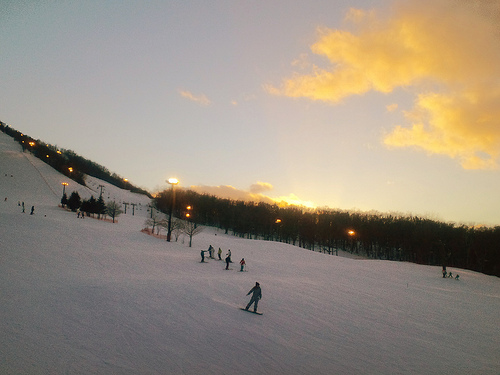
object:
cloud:
[262, 3, 497, 181]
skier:
[239, 257, 246, 272]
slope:
[1, 127, 499, 374]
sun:
[269, 194, 300, 209]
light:
[166, 175, 181, 187]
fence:
[138, 227, 175, 241]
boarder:
[241, 280, 263, 315]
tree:
[95, 192, 106, 219]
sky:
[2, 2, 499, 225]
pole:
[165, 184, 174, 245]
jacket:
[239, 258, 247, 265]